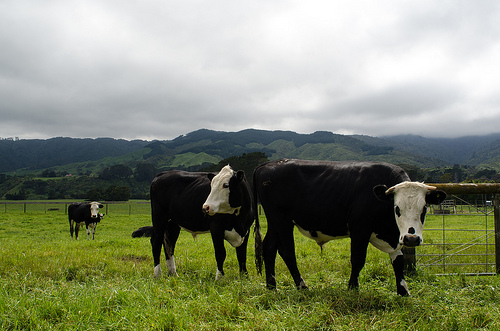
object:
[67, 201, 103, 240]
cow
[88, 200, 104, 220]
head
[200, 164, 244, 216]
head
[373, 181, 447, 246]
head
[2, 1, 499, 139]
sky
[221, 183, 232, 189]
eye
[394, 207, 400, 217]
eye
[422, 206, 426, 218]
eye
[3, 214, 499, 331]
grass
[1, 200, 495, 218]
fence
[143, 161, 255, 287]
cow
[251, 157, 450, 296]
cow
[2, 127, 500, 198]
mountainside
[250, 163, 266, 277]
tail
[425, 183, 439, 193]
horn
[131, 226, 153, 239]
cow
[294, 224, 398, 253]
underbelly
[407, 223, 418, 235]
spot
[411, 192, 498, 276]
gate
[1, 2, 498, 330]
scene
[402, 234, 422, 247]
nose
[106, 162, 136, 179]
trees